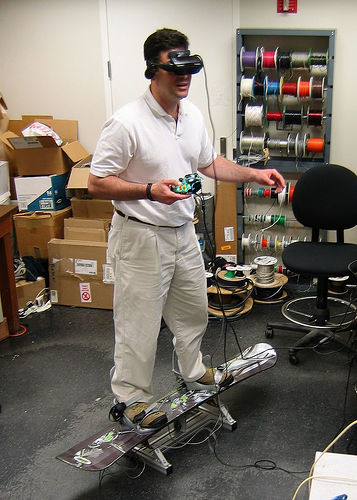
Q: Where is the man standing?
A: A game board.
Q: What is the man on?
A: Snowboard game.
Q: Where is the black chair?
A: Behind the man.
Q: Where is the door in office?
A: Behind the man.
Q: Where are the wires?
A: On snowboard.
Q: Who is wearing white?
A: The man.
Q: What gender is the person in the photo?
A: Male.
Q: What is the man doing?
A: Playing with a device.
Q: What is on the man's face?
A: Goggles.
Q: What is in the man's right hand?
A: A controller.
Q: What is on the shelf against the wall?
A: Wires.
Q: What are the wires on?
A: Spools.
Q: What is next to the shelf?
A: A door.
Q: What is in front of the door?
A: Boxes.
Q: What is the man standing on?
A: A board.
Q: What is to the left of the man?
A: A chair.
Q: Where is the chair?
A: On the right.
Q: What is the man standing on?
A: A snowboard.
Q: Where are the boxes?
A: Behind the man.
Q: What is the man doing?
A: Playing a video game.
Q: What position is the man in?
A: Standing.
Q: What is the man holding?
A: A controller.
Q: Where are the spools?
A: Behind the chair.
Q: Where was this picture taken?
A: Office.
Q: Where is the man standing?
A: Snowboard game.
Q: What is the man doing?
A: Testing game.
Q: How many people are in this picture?
A: 1.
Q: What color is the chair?
A: Black.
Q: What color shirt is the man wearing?
A: White.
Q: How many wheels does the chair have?
A: 5.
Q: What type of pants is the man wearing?
A: Khaki.